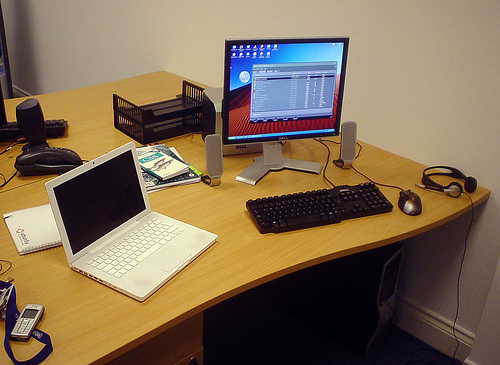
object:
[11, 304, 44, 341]
cell phone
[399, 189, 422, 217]
computer mouse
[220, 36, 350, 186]
computer tower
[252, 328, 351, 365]
floor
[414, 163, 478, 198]
head set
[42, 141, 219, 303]
laptop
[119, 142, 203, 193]
book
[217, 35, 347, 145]
computer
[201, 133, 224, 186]
speaker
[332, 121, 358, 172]
speaker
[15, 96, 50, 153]
speaker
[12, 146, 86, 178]
phone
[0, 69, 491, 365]
desk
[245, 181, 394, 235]
keyboard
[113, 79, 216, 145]
holder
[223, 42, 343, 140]
monitor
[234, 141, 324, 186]
base